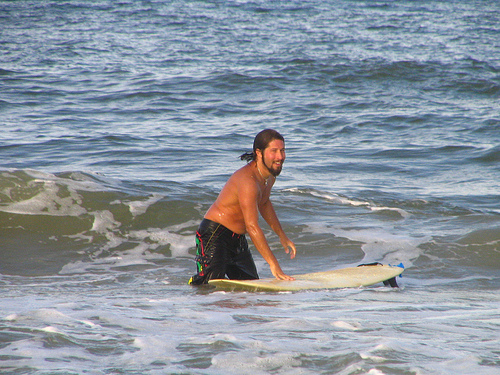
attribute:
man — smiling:
[197, 94, 324, 297]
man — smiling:
[237, 120, 291, 189]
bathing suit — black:
[186, 215, 261, 286]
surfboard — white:
[202, 254, 397, 296]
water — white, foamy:
[361, 203, 487, 245]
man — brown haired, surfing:
[188, 128, 299, 290]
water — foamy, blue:
[2, 2, 498, 370]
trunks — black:
[186, 216, 261, 286]